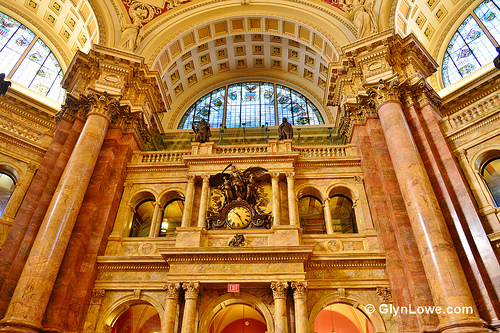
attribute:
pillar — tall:
[10, 76, 158, 331]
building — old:
[6, 7, 478, 306]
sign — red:
[223, 282, 239, 295]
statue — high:
[196, 119, 292, 144]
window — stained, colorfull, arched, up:
[165, 78, 320, 131]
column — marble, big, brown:
[360, 79, 499, 302]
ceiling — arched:
[140, 25, 391, 125]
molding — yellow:
[90, 10, 196, 133]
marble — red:
[362, 89, 454, 221]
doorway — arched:
[200, 294, 272, 331]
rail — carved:
[175, 223, 372, 238]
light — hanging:
[156, 201, 173, 235]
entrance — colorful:
[222, 320, 268, 332]